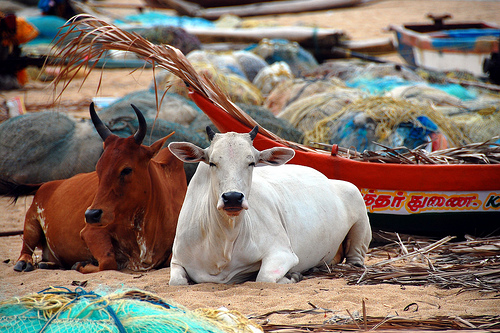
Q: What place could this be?
A: It is a beach.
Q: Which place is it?
A: It is a beach.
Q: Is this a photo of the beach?
A: Yes, it is showing the beach.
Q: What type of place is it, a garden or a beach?
A: It is a beach.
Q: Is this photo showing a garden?
A: No, the picture is showing a beach.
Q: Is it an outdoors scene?
A: Yes, it is outdoors.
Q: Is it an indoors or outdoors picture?
A: It is outdoors.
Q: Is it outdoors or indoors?
A: It is outdoors.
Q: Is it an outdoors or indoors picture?
A: It is outdoors.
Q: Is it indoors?
A: No, it is outdoors.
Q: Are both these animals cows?
A: No, they are cows and bulls.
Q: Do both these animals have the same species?
A: No, they are cows and bulls.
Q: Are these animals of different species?
A: Yes, they are cows and bulls.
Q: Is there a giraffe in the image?
A: No, there are no giraffes.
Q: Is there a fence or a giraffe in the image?
A: No, there are no giraffes or fences.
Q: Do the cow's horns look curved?
A: Yes, the horns are curved.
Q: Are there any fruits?
A: No, there are no fruits.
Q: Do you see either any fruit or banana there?
A: No, there are no fruits or bananas.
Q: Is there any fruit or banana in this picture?
A: No, there are no fruits or bananas.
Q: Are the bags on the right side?
A: Yes, the bags are on the right of the image.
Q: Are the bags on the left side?
A: No, the bags are on the right of the image.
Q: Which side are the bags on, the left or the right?
A: The bags are on the right of the image.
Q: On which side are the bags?
A: The bags are on the right of the image.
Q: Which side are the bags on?
A: The bags are on the right of the image.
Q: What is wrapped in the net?
A: The bags are wrapped in the net.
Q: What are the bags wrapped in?
A: The bags are wrapped in a net.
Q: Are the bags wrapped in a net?
A: Yes, the bags are wrapped in a net.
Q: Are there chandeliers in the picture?
A: No, there are no chandeliers.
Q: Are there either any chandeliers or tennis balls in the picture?
A: No, there are no chandeliers or tennis balls.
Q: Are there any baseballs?
A: No, there are no baseballs.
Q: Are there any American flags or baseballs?
A: No, there are no baseballs or American flags.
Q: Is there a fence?
A: No, there are no fences.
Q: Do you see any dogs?
A: No, there are no dogs.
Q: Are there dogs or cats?
A: No, there are no dogs or cats.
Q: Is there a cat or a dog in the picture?
A: No, there are no dogs or cats.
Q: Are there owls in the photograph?
A: No, there are no owls.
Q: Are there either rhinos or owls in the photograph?
A: No, there are no owls or rhinos.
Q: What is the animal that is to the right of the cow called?
A: The animal is a bull.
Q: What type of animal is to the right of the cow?
A: The animal is a bull.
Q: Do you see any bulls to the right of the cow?
A: Yes, there is a bull to the right of the cow.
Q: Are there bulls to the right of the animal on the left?
A: Yes, there is a bull to the right of the cow.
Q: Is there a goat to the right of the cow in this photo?
A: No, there is a bull to the right of the cow.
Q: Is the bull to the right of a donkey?
A: No, the bull is to the right of the cow.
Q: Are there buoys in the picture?
A: Yes, there are buoys.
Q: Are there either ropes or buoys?
A: Yes, there are buoys.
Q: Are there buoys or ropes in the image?
A: Yes, there are buoys.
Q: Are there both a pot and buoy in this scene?
A: No, there are buoys but no pots.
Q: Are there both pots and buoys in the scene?
A: No, there are buoys but no pots.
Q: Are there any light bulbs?
A: No, there are no light bulbs.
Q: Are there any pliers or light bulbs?
A: No, there are no light bulbs or pliers.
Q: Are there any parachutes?
A: No, there are no parachutes.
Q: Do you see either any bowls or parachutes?
A: No, there are no parachutes or bowls.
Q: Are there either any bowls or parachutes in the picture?
A: No, there are no parachutes or bowls.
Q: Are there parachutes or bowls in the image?
A: No, there are no parachutes or bowls.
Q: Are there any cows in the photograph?
A: Yes, there is a cow.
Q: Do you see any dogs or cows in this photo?
A: Yes, there is a cow.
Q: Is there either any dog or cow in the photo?
A: Yes, there is a cow.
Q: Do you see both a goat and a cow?
A: No, there is a cow but no goats.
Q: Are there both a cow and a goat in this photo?
A: No, there is a cow but no goats.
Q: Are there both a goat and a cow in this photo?
A: No, there is a cow but no goats.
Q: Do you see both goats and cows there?
A: No, there is a cow but no goats.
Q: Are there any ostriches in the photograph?
A: No, there are no ostriches.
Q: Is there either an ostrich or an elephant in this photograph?
A: No, there are no ostriches or elephants.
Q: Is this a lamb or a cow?
A: This is a cow.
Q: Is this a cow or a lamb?
A: This is a cow.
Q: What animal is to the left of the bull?
A: The animal is a cow.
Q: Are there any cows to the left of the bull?
A: Yes, there is a cow to the left of the bull.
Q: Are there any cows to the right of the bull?
A: No, the cow is to the left of the bull.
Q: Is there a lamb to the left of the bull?
A: No, there is a cow to the left of the bull.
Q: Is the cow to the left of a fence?
A: No, the cow is to the left of a bull.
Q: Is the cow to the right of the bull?
A: No, the cow is to the left of the bull.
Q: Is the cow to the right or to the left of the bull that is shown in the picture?
A: The cow is to the left of the bull.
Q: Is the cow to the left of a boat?
A: Yes, the cow is to the left of a boat.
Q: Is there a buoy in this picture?
A: Yes, there are buoys.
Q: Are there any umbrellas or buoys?
A: Yes, there are buoys.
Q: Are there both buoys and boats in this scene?
A: Yes, there are both buoys and a boat.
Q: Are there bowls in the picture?
A: No, there are no bowls.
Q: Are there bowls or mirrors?
A: No, there are no bowls or mirrors.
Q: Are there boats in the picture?
A: Yes, there is a boat.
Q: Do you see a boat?
A: Yes, there is a boat.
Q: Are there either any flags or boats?
A: Yes, there is a boat.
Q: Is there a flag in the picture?
A: No, there are no flags.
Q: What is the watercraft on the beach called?
A: The watercraft is a boat.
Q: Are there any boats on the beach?
A: Yes, there is a boat on the beach.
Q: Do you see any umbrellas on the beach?
A: No, there is a boat on the beach.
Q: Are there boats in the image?
A: Yes, there is a boat.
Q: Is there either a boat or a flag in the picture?
A: Yes, there is a boat.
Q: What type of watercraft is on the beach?
A: The watercraft is a boat.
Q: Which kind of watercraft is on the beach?
A: The watercraft is a boat.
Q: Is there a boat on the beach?
A: Yes, there is a boat on the beach.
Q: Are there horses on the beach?
A: No, there is a boat on the beach.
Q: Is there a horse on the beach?
A: No, there is a boat on the beach.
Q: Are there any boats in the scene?
A: Yes, there is a boat.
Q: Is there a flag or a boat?
A: Yes, there is a boat.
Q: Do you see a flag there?
A: No, there are no flags.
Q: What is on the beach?
A: The boat is on the beach.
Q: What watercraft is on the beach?
A: The watercraft is a boat.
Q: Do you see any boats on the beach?
A: Yes, there is a boat on the beach.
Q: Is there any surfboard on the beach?
A: No, there is a boat on the beach.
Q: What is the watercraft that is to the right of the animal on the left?
A: The watercraft is a boat.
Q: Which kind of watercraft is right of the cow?
A: The watercraft is a boat.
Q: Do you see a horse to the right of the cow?
A: No, there is a boat to the right of the cow.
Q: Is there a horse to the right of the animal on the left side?
A: No, there is a boat to the right of the cow.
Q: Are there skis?
A: No, there are no skis.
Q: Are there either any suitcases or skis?
A: No, there are no skis or suitcases.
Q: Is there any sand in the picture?
A: Yes, there is sand.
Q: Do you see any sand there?
A: Yes, there is sand.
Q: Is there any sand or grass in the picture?
A: Yes, there is sand.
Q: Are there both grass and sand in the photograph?
A: No, there is sand but no grass.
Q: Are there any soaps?
A: No, there are no soaps.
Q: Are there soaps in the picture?
A: No, there are no soaps.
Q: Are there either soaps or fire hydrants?
A: No, there are no soaps or fire hydrants.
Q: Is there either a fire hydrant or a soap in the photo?
A: No, there are no soaps or fire hydrants.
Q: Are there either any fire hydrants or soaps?
A: No, there are no soaps or fire hydrants.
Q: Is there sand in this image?
A: Yes, there is sand.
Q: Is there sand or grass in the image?
A: Yes, there is sand.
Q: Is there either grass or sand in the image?
A: Yes, there is sand.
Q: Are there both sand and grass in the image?
A: No, there is sand but no grass.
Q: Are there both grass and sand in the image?
A: No, there is sand but no grass.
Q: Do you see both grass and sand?
A: No, there is sand but no grass.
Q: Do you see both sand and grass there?
A: No, there is sand but no grass.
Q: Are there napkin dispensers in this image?
A: No, there are no napkin dispensers.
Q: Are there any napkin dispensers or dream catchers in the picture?
A: No, there are no napkin dispensers or dream catchers.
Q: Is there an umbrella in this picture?
A: No, there are no umbrellas.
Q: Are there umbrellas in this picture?
A: No, there are no umbrellas.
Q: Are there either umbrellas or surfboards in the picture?
A: No, there are no umbrellas or surfboards.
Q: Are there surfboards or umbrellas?
A: No, there are no umbrellas or surfboards.